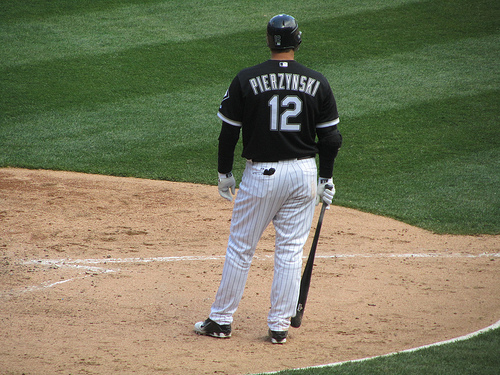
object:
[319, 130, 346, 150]
elbow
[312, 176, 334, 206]
glove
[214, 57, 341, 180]
jersey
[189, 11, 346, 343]
baseball player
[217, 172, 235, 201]
left hand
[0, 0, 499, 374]
grass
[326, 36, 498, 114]
stripe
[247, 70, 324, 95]
letters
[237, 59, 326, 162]
back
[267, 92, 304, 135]
12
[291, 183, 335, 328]
baseball bat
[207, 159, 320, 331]
baseball pants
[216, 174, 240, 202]
gloves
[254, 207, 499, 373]
baseball infield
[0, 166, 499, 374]
ground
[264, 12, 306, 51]
helmet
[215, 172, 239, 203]
hand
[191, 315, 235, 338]
shoe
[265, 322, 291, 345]
shoe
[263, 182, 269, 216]
stripe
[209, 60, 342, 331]
uniform